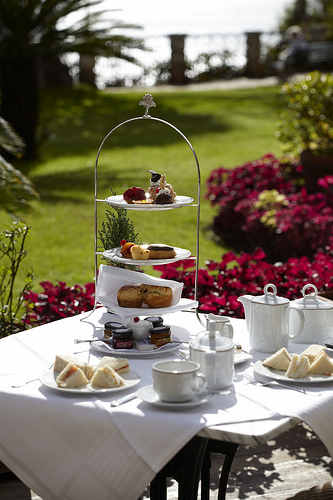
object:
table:
[0, 309, 332, 499]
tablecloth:
[0, 307, 332, 499]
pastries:
[129, 243, 151, 261]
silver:
[137, 90, 156, 117]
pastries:
[117, 284, 144, 309]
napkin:
[95, 264, 184, 324]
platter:
[103, 194, 194, 214]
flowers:
[214, 297, 226, 307]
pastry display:
[74, 92, 206, 358]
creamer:
[203, 313, 233, 338]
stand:
[91, 91, 200, 334]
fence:
[57, 25, 333, 87]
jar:
[144, 317, 163, 326]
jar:
[148, 324, 171, 347]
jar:
[111, 325, 133, 350]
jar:
[103, 321, 124, 346]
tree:
[0, 0, 154, 163]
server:
[203, 312, 233, 336]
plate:
[252, 355, 332, 384]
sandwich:
[262, 347, 291, 372]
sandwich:
[283, 354, 309, 380]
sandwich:
[308, 350, 332, 374]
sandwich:
[300, 342, 327, 361]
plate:
[39, 367, 140, 396]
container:
[127, 319, 152, 341]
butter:
[134, 320, 152, 337]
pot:
[235, 283, 305, 354]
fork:
[261, 380, 307, 395]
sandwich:
[89, 363, 124, 386]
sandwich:
[54, 362, 86, 388]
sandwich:
[92, 354, 129, 374]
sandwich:
[52, 354, 91, 379]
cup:
[151, 358, 208, 403]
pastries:
[144, 244, 178, 259]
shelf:
[90, 321, 188, 356]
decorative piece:
[138, 93, 155, 115]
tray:
[73, 90, 203, 358]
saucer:
[135, 384, 208, 411]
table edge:
[0, 392, 254, 449]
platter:
[102, 243, 190, 265]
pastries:
[120, 237, 135, 259]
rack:
[76, 91, 202, 358]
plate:
[88, 335, 182, 357]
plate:
[97, 295, 194, 315]